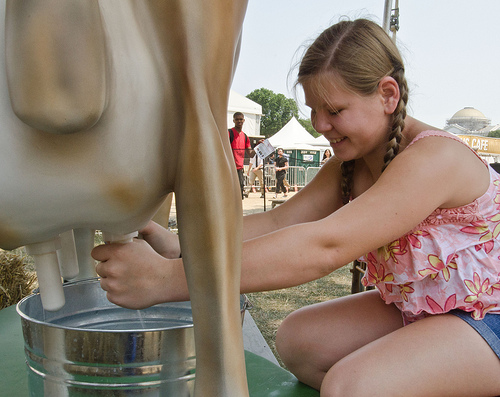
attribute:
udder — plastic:
[30, 246, 70, 308]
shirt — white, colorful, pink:
[397, 230, 500, 304]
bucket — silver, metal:
[16, 311, 191, 396]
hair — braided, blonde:
[291, 18, 408, 79]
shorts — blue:
[466, 316, 500, 351]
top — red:
[232, 132, 244, 164]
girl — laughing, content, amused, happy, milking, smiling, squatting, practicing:
[252, 14, 499, 395]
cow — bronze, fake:
[3, 1, 249, 396]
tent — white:
[261, 116, 317, 148]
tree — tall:
[252, 89, 295, 124]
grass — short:
[252, 291, 320, 310]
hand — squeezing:
[92, 241, 158, 311]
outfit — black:
[273, 160, 288, 193]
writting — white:
[468, 139, 489, 152]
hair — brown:
[233, 112, 242, 118]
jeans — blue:
[474, 318, 497, 347]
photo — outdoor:
[0, 3, 499, 396]